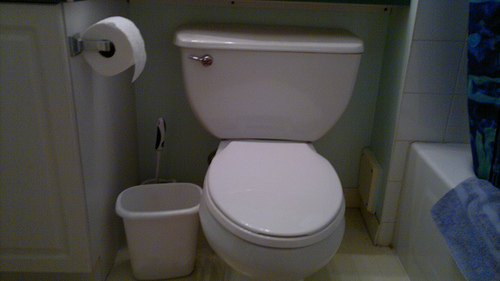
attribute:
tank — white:
[182, 42, 355, 138]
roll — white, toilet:
[80, 17, 146, 75]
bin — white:
[120, 180, 203, 270]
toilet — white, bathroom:
[173, 36, 362, 277]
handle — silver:
[189, 50, 215, 68]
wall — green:
[196, 7, 347, 23]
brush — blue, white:
[149, 112, 167, 180]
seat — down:
[202, 138, 343, 247]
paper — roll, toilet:
[83, 14, 145, 77]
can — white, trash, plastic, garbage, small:
[115, 181, 205, 279]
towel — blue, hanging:
[436, 180, 498, 264]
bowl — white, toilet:
[200, 138, 354, 278]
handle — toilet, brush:
[148, 115, 171, 181]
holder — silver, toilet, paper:
[65, 31, 113, 58]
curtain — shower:
[460, 7, 493, 195]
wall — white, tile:
[385, 2, 473, 265]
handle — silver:
[185, 48, 215, 71]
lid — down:
[205, 136, 345, 243]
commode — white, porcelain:
[170, 18, 379, 278]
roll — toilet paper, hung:
[78, 10, 164, 81]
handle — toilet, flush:
[190, 48, 220, 68]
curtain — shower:
[460, 5, 498, 191]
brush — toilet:
[149, 114, 181, 188]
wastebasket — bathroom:
[112, 178, 205, 278]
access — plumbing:
[357, 152, 383, 228]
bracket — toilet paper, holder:
[67, 25, 115, 65]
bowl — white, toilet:
[173, 17, 383, 277]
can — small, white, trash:
[107, 177, 214, 276]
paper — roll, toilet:
[75, 14, 149, 80]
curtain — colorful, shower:
[449, 4, 496, 189]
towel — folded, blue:
[428, 168, 494, 279]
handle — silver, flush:
[186, 47, 215, 67]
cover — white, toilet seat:
[207, 134, 341, 251]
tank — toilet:
[172, 19, 362, 139]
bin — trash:
[109, 179, 220, 279]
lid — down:
[203, 139, 348, 236]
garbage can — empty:
[110, 178, 208, 278]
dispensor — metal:
[61, 31, 111, 60]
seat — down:
[204, 134, 354, 239]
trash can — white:
[112, 174, 204, 274]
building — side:
[50, 101, 123, 181]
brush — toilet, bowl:
[149, 115, 170, 169]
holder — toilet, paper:
[69, 31, 108, 57]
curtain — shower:
[469, 0, 499, 181]